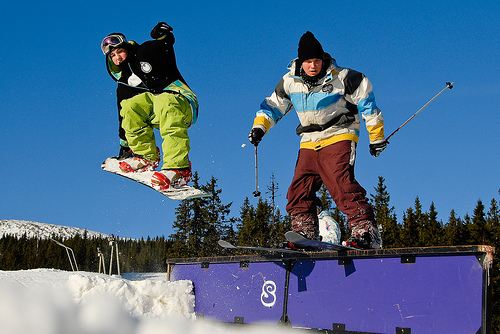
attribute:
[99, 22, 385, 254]
people — jumping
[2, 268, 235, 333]
snow — white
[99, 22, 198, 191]
person — young, jumping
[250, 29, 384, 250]
person — skiing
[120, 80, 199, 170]
pants — green, maroon, crimson, dark red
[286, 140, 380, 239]
pants — brown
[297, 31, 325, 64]
beanie — black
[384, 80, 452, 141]
poles — silver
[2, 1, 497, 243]
sky — blue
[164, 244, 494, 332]
platform — purple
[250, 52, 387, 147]
coat — blue, white, multi-colored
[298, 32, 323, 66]
cap — black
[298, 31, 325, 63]
hat — black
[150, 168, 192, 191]
boots — red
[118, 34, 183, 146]
coat — black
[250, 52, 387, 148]
jacket — blue